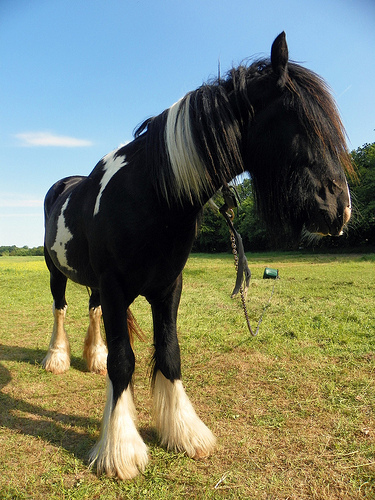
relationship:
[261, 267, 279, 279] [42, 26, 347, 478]
bucket behind horse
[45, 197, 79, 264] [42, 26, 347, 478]
spot on horse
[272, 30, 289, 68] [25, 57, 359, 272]
ear on horse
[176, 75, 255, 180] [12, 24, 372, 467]
mane on horse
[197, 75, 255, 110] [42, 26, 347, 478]
mane on horse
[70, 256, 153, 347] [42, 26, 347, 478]
tail on horse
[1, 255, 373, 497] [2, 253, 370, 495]
grass on field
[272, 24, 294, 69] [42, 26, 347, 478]
ear on horse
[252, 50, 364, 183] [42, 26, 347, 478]
hair on horse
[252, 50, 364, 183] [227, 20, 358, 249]
hair on head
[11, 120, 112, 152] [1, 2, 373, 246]
cloud in sky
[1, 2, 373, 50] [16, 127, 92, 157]
sky behind cloud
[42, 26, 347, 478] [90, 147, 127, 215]
horse has spot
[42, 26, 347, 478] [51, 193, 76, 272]
horse has spot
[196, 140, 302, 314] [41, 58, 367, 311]
chain around horse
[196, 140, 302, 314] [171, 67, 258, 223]
chain around neck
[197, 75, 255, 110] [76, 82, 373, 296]
mane going downward on horse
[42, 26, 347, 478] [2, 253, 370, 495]
horse standing in field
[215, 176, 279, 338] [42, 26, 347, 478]
chain hanging from horse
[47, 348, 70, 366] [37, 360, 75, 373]
white hair covering hoof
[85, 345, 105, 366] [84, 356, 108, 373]
white hair covering hoof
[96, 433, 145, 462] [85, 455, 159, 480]
white hair covering hoof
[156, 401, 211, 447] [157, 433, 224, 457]
white hair covering hoof